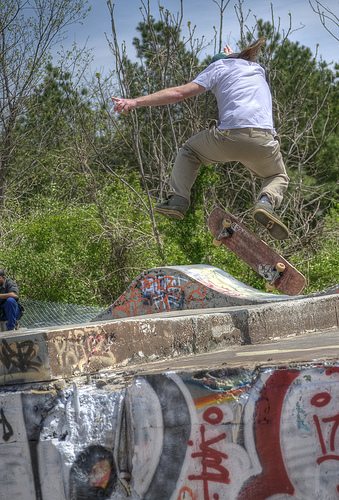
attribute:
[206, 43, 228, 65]
cap — green 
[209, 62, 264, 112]
grey shirt — gray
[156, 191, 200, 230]
tan shoes — gray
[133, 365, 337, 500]
graffiti on wall — multicolor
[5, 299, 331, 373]
concrete ramp — concrete  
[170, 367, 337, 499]
red letter painted — red 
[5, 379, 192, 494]
spray paint — red 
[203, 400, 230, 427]
letter painted — red 